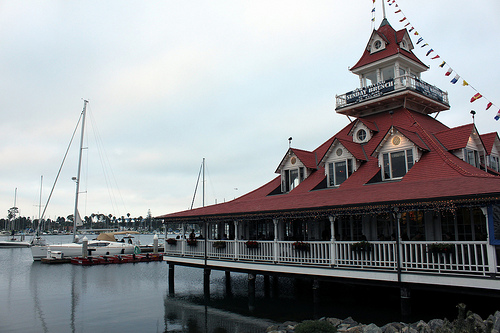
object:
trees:
[3, 213, 161, 235]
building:
[149, 0, 499, 299]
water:
[1, 235, 264, 332]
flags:
[370, 2, 499, 119]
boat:
[25, 235, 145, 265]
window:
[287, 167, 310, 193]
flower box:
[293, 241, 312, 251]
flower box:
[347, 242, 374, 252]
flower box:
[427, 240, 457, 252]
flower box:
[245, 240, 265, 252]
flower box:
[210, 240, 227, 252]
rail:
[160, 236, 485, 274]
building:
[163, 15, 487, 275]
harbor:
[7, 202, 487, 320]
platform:
[329, 74, 451, 119]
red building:
[154, 20, 494, 285]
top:
[327, 7, 450, 110]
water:
[18, 267, 93, 311]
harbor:
[3, 70, 163, 251]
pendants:
[387, 2, 499, 118]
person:
[188, 227, 204, 246]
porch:
[160, 236, 497, 288]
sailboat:
[4, 187, 31, 255]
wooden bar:
[273, 216, 279, 262]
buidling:
[152, 2, 497, 328]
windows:
[316, 154, 357, 193]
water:
[0, 234, 218, 330]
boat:
[28, 95, 166, 266]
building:
[168, 37, 496, 296]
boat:
[30, 104, 156, 279]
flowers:
[343, 234, 376, 258]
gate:
[241, 230, 484, 266]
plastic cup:
[417, 23, 484, 92]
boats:
[4, 221, 165, 262]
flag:
[470, 91, 481, 103]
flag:
[445, 66, 455, 76]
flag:
[492, 104, 498, 121]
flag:
[424, 49, 435, 56]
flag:
[392, 9, 402, 16]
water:
[0, 232, 490, 331]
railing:
[323, 74, 448, 112]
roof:
[347, 21, 424, 74]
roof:
[162, 103, 497, 233]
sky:
[144, 57, 273, 150]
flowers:
[290, 240, 311, 252]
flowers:
[243, 238, 263, 250]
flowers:
[214, 240, 228, 252]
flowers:
[187, 238, 200, 249]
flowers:
[168, 238, 178, 247]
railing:
[163, 235, 497, 280]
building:
[32, 89, 494, 318]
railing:
[203, 222, 452, 296]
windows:
[269, 143, 427, 192]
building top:
[347, 15, 456, 101]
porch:
[153, 230, 498, 311]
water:
[6, 248, 182, 329]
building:
[168, 196, 497, 295]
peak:
[366, 24, 393, 59]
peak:
[269, 145, 311, 180]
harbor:
[5, 234, 218, 328]